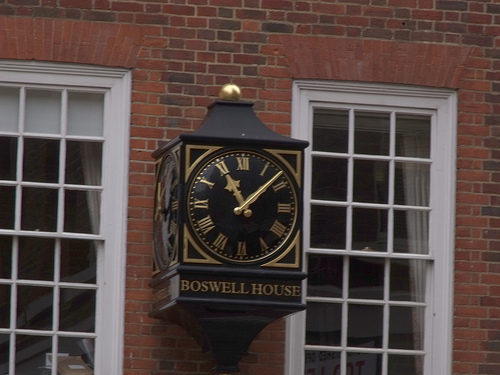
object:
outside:
[0, 0, 485, 371]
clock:
[149, 83, 308, 354]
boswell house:
[179, 278, 303, 297]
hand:
[224, 171, 252, 219]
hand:
[233, 169, 283, 214]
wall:
[0, 0, 499, 375]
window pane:
[0, 61, 134, 375]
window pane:
[283, 78, 457, 374]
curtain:
[78, 139, 107, 244]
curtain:
[400, 130, 429, 374]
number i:
[258, 161, 273, 178]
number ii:
[273, 179, 287, 192]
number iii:
[276, 201, 293, 214]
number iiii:
[269, 219, 288, 237]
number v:
[258, 235, 270, 250]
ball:
[220, 84, 242, 100]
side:
[152, 136, 181, 307]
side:
[180, 138, 302, 306]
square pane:
[63, 91, 105, 137]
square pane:
[23, 88, 64, 136]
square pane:
[62, 139, 102, 187]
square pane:
[22, 136, 62, 184]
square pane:
[19, 184, 58, 232]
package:
[59, 350, 88, 373]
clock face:
[184, 144, 300, 265]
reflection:
[364, 141, 435, 266]